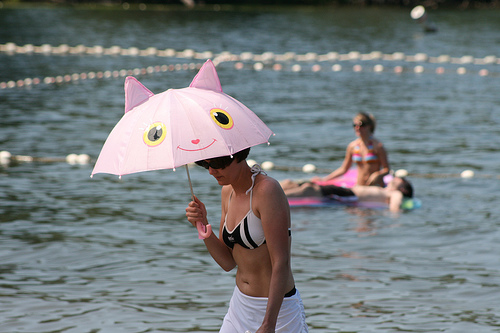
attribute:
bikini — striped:
[356, 150, 379, 186]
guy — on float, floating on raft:
[314, 190, 432, 217]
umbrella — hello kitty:
[71, 65, 304, 149]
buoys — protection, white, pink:
[283, 53, 456, 82]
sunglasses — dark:
[192, 159, 253, 174]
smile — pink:
[178, 141, 228, 166]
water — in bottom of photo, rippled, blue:
[245, 23, 379, 36]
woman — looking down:
[177, 157, 323, 327]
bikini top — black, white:
[212, 203, 304, 253]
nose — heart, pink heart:
[180, 129, 206, 149]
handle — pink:
[193, 220, 217, 234]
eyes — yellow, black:
[143, 112, 242, 124]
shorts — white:
[218, 293, 311, 325]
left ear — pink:
[111, 74, 161, 115]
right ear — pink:
[183, 63, 239, 96]